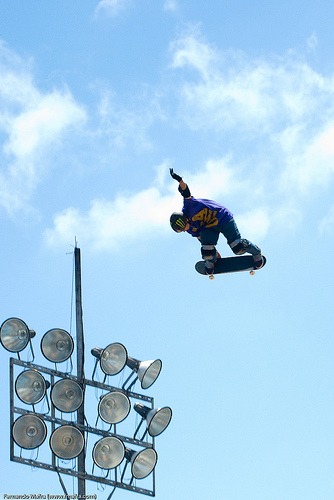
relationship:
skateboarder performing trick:
[166, 168, 268, 278] [191, 252, 267, 279]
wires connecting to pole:
[2, 232, 159, 499] [73, 245, 88, 499]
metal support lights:
[9, 354, 159, 498] [3, 315, 173, 499]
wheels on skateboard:
[206, 269, 256, 278] [191, 252, 267, 279]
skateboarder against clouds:
[166, 168, 268, 278] [2, 2, 334, 284]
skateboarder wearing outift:
[166, 168, 268, 278] [181, 198, 256, 258]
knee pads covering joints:
[198, 243, 250, 260] [194, 239, 250, 260]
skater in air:
[166, 168, 268, 278] [2, 2, 332, 500]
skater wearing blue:
[166, 168, 268, 278] [182, 196, 230, 237]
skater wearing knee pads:
[166, 168, 268, 278] [198, 243, 250, 260]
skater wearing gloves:
[166, 168, 268, 278] [170, 169, 181, 183]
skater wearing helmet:
[166, 168, 268, 278] [169, 213, 184, 234]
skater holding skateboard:
[166, 168, 268, 278] [193, 254, 266, 279]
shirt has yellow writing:
[182, 196, 229, 233] [193, 208, 219, 229]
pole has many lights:
[73, 245, 88, 499] [3, 315, 173, 499]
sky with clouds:
[2, 2, 332, 500] [2, 2, 334, 284]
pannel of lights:
[9, 354, 159, 498] [3, 315, 173, 499]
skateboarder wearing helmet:
[166, 168, 268, 278] [169, 213, 184, 234]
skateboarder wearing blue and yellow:
[166, 168, 268, 278] [182, 196, 230, 237]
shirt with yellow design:
[182, 196, 229, 233] [193, 208, 219, 229]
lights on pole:
[3, 315, 173, 499] [73, 245, 88, 499]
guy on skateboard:
[166, 168, 268, 278] [193, 254, 266, 279]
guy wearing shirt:
[166, 168, 268, 278] [182, 196, 229, 233]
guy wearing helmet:
[166, 168, 268, 278] [169, 213, 184, 234]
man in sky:
[166, 168, 268, 278] [2, 2, 332, 500]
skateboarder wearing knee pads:
[166, 168, 268, 278] [198, 243, 250, 260]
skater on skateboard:
[166, 168, 268, 278] [193, 254, 266, 279]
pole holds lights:
[73, 245, 88, 499] [3, 315, 173, 499]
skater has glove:
[166, 168, 268, 278] [167, 166, 180, 178]